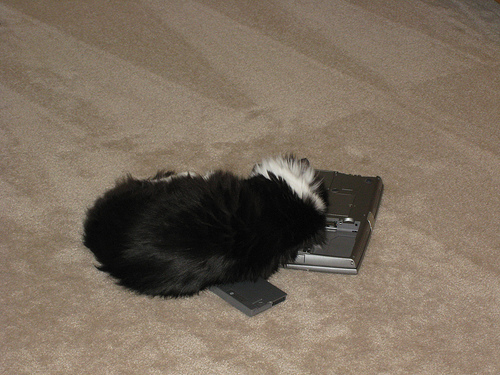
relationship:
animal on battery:
[78, 151, 333, 302] [209, 280, 286, 316]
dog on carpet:
[41, 144, 343, 318] [424, 47, 475, 136]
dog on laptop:
[71, 142, 338, 304] [279, 170, 382, 275]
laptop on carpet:
[279, 170, 382, 275] [385, 1, 484, 371]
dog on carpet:
[78, 139, 333, 312] [2, 2, 483, 145]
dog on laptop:
[78, 139, 333, 312] [316, 166, 385, 275]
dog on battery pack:
[78, 151, 333, 300] [309, 161, 383, 275]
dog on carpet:
[78, 151, 333, 300] [2, 2, 483, 145]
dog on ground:
[78, 151, 333, 300] [304, 97, 379, 142]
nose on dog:
[296, 152, 311, 168] [78, 151, 333, 300]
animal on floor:
[78, 151, 333, 302] [380, 147, 441, 319]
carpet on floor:
[86, 74, 119, 129] [382, 240, 492, 364]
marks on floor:
[283, 65, 498, 272] [6, 2, 498, 364]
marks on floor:
[0, 0, 500, 113] [6, 2, 498, 364]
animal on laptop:
[78, 151, 333, 302] [316, 166, 385, 275]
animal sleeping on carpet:
[78, 151, 333, 302] [391, 88, 493, 372]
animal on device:
[78, 151, 333, 302] [280, 169, 383, 275]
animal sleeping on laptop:
[78, 151, 333, 302] [279, 170, 382, 275]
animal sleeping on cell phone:
[78, 151, 333, 302] [208, 274, 292, 317]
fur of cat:
[82, 152, 330, 305] [38, 85, 315, 310]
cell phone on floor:
[208, 274, 286, 313] [6, 2, 498, 364]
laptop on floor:
[289, 170, 382, 277] [6, 2, 498, 364]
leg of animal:
[147, 152, 211, 200] [78, 151, 333, 302]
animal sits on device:
[87, 139, 332, 290] [294, 169, 382, 271]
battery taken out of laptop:
[210, 265, 287, 315] [293, 145, 389, 280]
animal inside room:
[78, 151, 333, 302] [4, 3, 498, 372]